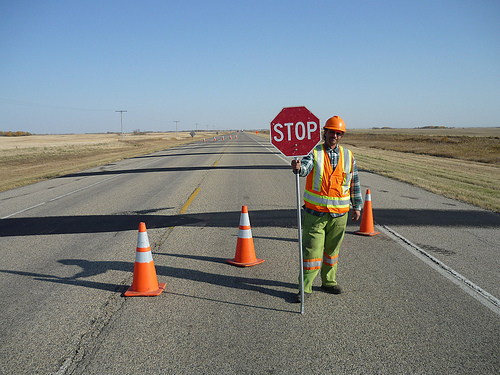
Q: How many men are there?
A: 1.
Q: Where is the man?
A: Street.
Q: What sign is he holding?
A: Stop.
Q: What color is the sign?
A: Red.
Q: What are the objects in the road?
A: Cones.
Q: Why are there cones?
A: Safety.